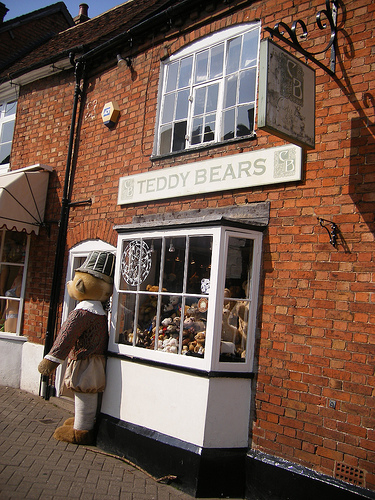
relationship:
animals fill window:
[122, 279, 251, 361] [105, 229, 261, 379]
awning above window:
[0, 165, 54, 238] [2, 226, 32, 337]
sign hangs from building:
[255, 39, 315, 151] [0, 2, 374, 500]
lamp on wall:
[113, 54, 132, 75] [1, 1, 373, 492]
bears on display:
[125, 284, 250, 361] [115, 237, 255, 376]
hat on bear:
[69, 246, 114, 286] [39, 250, 117, 445]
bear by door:
[39, 250, 117, 445] [56, 238, 116, 399]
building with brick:
[0, 2, 374, 500] [287, 306, 315, 315]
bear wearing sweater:
[39, 250, 117, 445] [41, 300, 114, 367]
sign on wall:
[255, 39, 315, 151] [1, 1, 373, 492]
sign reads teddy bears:
[117, 141, 304, 205] [134, 158, 266, 198]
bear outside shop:
[39, 250, 117, 445] [54, 150, 372, 492]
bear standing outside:
[39, 250, 117, 445] [0, 2, 374, 500]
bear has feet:
[39, 250, 117, 445] [54, 417, 98, 447]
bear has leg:
[39, 250, 117, 445] [65, 352, 105, 432]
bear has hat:
[39, 250, 117, 445] [69, 246, 114, 286]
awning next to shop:
[0, 165, 54, 238] [54, 150, 372, 492]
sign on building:
[99, 104, 122, 128] [0, 2, 374, 500]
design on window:
[118, 240, 152, 284] [105, 229, 261, 379]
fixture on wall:
[312, 217, 337, 251] [1, 1, 373, 492]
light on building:
[111, 52, 134, 74] [0, 2, 374, 500]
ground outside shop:
[2, 384, 197, 498] [54, 150, 372, 492]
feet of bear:
[54, 417, 98, 447] [39, 250, 117, 445]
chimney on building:
[72, 4, 93, 25] [0, 2, 374, 500]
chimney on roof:
[72, 4, 93, 25] [0, 1, 180, 89]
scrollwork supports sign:
[263, 2, 340, 81] [255, 39, 315, 151]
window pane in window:
[165, 60, 178, 92] [151, 23, 261, 162]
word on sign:
[137, 158, 269, 198] [117, 141, 304, 205]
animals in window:
[122, 279, 251, 361] [105, 229, 261, 379]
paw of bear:
[37, 357, 59, 380] [39, 250, 117, 445]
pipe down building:
[39, 52, 86, 402] [0, 2, 374, 500]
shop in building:
[54, 150, 372, 492] [0, 2, 374, 500]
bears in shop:
[125, 284, 250, 361] [54, 150, 372, 492]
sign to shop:
[117, 141, 304, 205] [54, 150, 372, 492]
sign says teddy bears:
[117, 141, 304, 205] [134, 158, 266, 198]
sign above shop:
[255, 39, 315, 151] [54, 150, 372, 492]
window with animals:
[105, 229, 261, 379] [122, 279, 251, 361]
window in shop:
[105, 229, 261, 379] [54, 150, 372, 492]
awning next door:
[0, 165, 54, 238] [56, 238, 116, 399]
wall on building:
[1, 1, 373, 492] [0, 2, 374, 500]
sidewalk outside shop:
[2, 387, 204, 499] [54, 150, 372, 492]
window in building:
[1, 89, 21, 171] [0, 2, 374, 500]